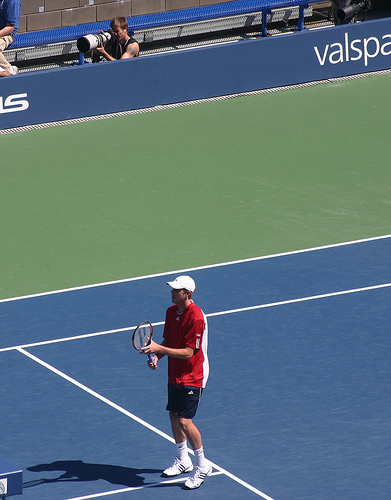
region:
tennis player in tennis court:
[128, 263, 222, 495]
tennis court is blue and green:
[0, 116, 389, 498]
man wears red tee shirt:
[122, 266, 230, 491]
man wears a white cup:
[122, 263, 235, 494]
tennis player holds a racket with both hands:
[114, 265, 233, 488]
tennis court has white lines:
[0, 216, 389, 496]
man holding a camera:
[70, 11, 141, 69]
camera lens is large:
[71, 26, 111, 65]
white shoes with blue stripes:
[158, 458, 217, 495]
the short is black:
[159, 382, 207, 421]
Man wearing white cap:
[165, 273, 194, 309]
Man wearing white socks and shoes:
[162, 439, 212, 489]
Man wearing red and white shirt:
[159, 273, 209, 386]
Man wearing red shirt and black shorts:
[161, 276, 204, 423]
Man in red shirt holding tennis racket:
[132, 274, 210, 391]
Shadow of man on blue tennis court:
[22, 456, 163, 494]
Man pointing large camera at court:
[74, 14, 142, 62]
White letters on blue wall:
[313, 32, 389, 68]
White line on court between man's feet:
[148, 457, 225, 489]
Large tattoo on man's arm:
[127, 45, 137, 55]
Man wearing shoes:
[161, 455, 220, 490]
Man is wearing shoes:
[159, 451, 218, 494]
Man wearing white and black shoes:
[161, 454, 215, 491]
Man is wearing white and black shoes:
[160, 454, 215, 491]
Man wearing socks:
[174, 436, 208, 470]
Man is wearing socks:
[170, 438, 207, 467]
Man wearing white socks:
[172, 439, 211, 465]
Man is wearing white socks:
[174, 437, 211, 467]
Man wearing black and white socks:
[166, 380, 207, 421]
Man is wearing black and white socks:
[159, 376, 208, 419]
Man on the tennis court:
[139, 274, 211, 488]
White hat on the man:
[165, 274, 196, 292]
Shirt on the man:
[161, 299, 209, 387]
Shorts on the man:
[164, 382, 202, 419]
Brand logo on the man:
[186, 388, 194, 396]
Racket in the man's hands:
[131, 320, 155, 365]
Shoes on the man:
[160, 458, 211, 490]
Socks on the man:
[175, 441, 207, 468]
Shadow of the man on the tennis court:
[21, 458, 189, 490]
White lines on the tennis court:
[2, 233, 390, 498]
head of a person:
[158, 261, 209, 302]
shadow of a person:
[44, 450, 140, 477]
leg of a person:
[171, 438, 187, 456]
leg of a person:
[183, 405, 215, 451]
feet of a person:
[165, 457, 202, 483]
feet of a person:
[180, 452, 233, 497]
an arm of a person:
[155, 333, 193, 368]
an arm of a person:
[143, 323, 168, 363]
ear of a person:
[178, 279, 200, 302]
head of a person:
[103, 12, 142, 48]